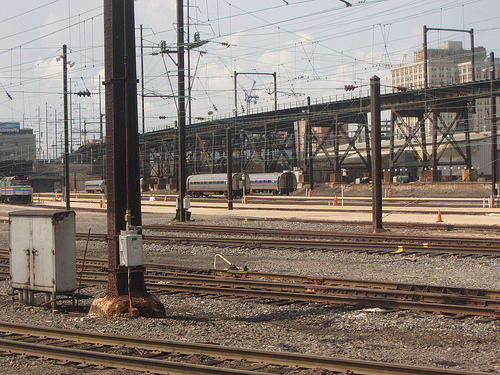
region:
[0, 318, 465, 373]
a set of train tracks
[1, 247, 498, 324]
a set of train tracks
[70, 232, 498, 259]
a set of train tracks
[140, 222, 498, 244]
a set of train tracks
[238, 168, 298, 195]
a silver passenger train car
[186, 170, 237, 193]
a silver passenger train car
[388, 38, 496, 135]
large building in distance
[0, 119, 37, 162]
large building in distance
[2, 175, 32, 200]
a silver red white and blue train engine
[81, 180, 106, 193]
a silver passenger train car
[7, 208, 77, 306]
A gray utility box with two doors.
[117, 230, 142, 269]
A gray meter box on a rusty metal pole.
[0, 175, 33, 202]
A train car with blue and red stripes.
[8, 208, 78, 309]
A gray box next to a metal pole.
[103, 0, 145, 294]
A big rusty pole with a gray meter on it.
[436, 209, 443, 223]
A orange construction cone.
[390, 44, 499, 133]
A large white building in the background.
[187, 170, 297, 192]
Two train cars side by side.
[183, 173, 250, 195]
A train car in front of another train car.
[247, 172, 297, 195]
A train car behind another train car.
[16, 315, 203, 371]
it is a train track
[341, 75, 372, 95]
it is a spool insulator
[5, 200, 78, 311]
track control box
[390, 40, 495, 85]
it is a bulding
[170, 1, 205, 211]
it is electrical poste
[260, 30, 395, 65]
it is a electric power line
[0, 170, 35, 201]
it is train engine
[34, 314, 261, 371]
small stones in railway track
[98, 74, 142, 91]
it is a poste clamp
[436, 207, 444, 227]
it is a road divider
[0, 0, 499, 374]
train yard, switchyard, rail yard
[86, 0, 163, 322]
power pole, power box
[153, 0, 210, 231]
power pole, dual power box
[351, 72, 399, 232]
pole, probably just to hold wires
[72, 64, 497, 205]
railyard bridge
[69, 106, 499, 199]
trestle parts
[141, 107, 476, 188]
sway braces [x] & sills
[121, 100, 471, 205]
multiple straight tangents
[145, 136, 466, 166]
multiple sills [straight across pieces]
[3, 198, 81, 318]
old railroad switchbox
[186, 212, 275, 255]
set of train tracks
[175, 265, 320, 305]
set of train tracks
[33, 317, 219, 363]
set of train tracks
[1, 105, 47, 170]
building in the distance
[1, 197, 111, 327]
grey electric box by tracks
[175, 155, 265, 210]
train on train tracks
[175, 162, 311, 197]
grey train on tracks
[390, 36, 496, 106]
tall building in distance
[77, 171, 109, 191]
grey train on tracks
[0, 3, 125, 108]
assortment of wires strung